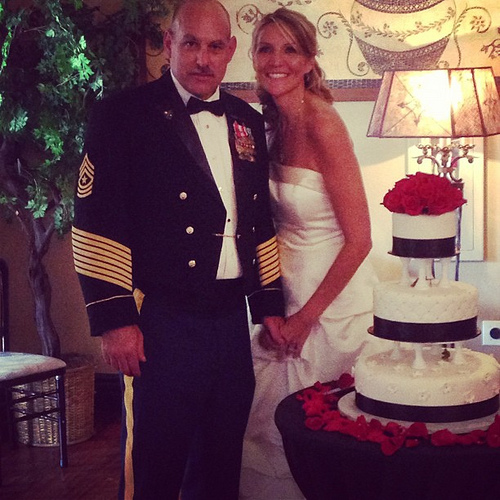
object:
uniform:
[68, 66, 284, 499]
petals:
[296, 372, 497, 456]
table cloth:
[272, 388, 498, 498]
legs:
[54, 369, 68, 468]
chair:
[0, 256, 75, 467]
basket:
[13, 352, 96, 450]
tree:
[0, 1, 105, 362]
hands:
[256, 317, 310, 363]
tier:
[351, 347, 499, 425]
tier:
[367, 280, 478, 342]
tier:
[383, 211, 460, 257]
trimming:
[354, 394, 499, 425]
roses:
[379, 171, 468, 216]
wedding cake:
[339, 213, 497, 432]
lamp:
[365, 66, 496, 182]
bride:
[235, 7, 382, 500]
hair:
[245, 11, 333, 163]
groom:
[72, 0, 283, 498]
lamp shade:
[362, 68, 500, 140]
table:
[272, 378, 500, 499]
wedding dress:
[239, 155, 386, 500]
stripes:
[69, 223, 134, 293]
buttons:
[188, 260, 197, 268]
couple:
[69, 0, 387, 498]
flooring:
[0, 419, 124, 500]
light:
[421, 86, 462, 115]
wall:
[146, 0, 499, 363]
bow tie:
[186, 96, 228, 118]